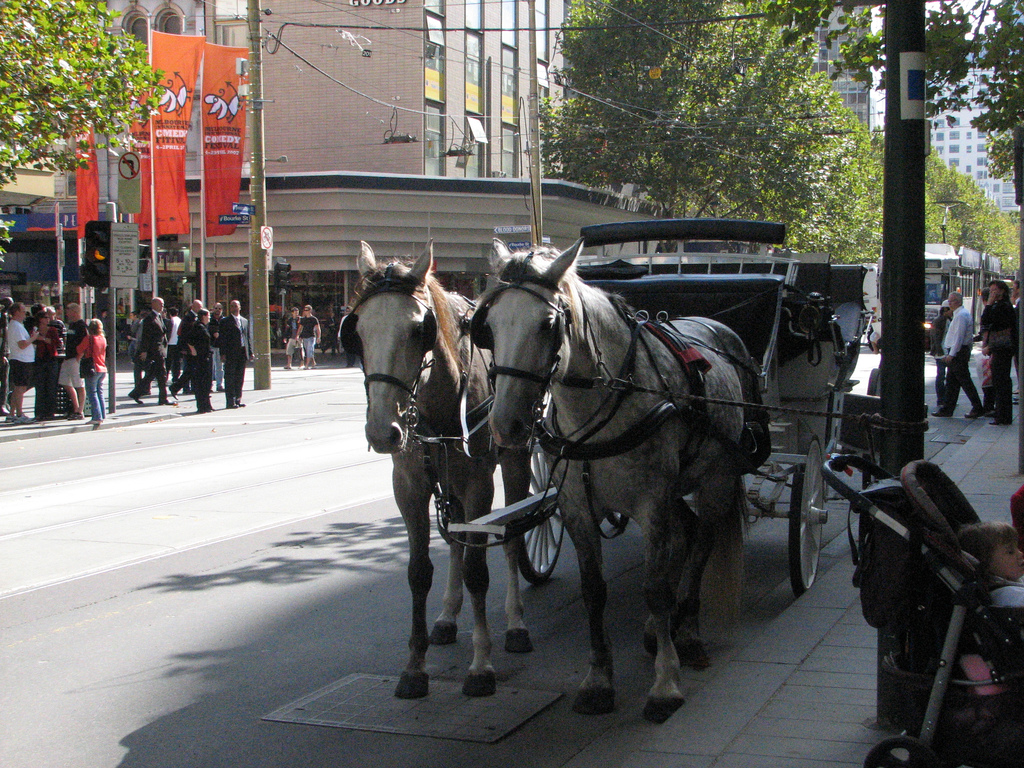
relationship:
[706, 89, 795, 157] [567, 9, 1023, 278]
leaves on tree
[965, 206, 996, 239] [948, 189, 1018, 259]
leaves in tree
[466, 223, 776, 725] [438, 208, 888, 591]
horse in front of carriage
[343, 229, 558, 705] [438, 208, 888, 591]
horse in front of carriage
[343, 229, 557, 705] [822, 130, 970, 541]
horse on pole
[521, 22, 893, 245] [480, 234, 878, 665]
tree behind carriage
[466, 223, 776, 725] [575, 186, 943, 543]
horse with carriage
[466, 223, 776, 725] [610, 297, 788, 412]
horse with cloth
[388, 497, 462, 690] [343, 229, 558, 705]
leg of horse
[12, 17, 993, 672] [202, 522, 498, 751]
view  shadow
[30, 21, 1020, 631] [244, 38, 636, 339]
view  building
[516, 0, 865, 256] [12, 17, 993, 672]
tree  view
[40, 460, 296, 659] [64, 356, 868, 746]
lines in road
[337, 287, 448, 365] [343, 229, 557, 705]
blinders around horse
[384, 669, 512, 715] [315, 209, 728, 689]
foot of horse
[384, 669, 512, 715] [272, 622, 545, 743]
foot on panel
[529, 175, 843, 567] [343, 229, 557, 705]
carriage drawn by horse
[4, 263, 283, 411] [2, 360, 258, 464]
people on sidewalk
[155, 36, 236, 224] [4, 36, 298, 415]
banners in front of building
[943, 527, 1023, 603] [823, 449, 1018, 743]
child in stroller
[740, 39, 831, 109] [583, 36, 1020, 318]
leaf on tree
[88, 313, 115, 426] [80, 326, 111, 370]
woman wearing jacket